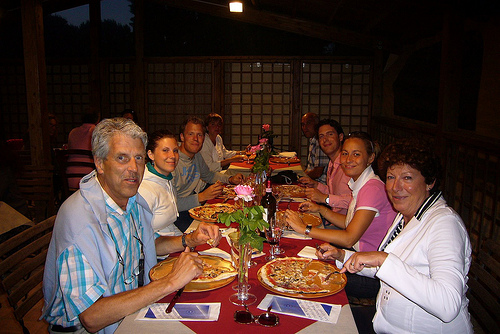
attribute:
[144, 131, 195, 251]
woman — smiling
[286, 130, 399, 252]
woman — smiling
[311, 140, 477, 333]
woman — smiling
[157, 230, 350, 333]
tablecloth — red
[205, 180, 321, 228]
tablecloth — red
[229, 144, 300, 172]
tablecloth — red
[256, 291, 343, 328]
napkin — blue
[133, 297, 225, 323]
napkin — blue